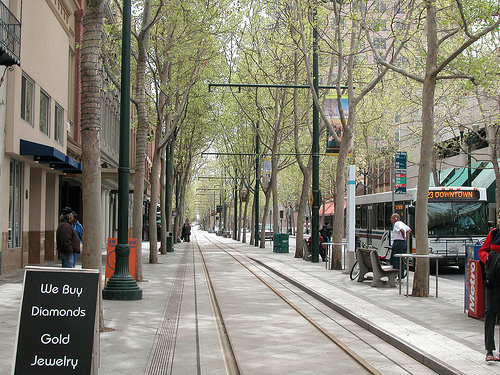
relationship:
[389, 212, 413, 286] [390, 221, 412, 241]
man wearing shirt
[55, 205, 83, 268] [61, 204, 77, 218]
man in hat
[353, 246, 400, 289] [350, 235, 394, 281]
bench by bike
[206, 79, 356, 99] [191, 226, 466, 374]
cable above tracks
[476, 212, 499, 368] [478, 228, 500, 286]
person in jacket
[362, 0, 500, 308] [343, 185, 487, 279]
tree near bus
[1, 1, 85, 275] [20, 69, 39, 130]
building has window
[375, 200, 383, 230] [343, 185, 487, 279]
window on bus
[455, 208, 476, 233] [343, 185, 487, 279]
man driving bus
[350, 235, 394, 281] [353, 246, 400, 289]
bike against bench